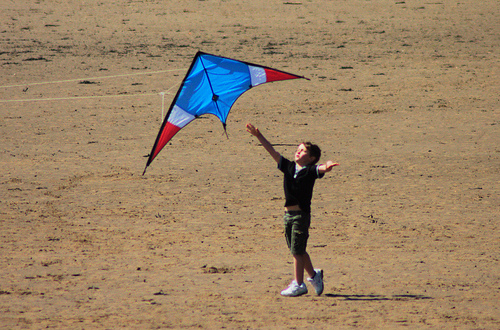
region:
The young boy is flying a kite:
[148, 42, 373, 313]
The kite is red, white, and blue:
[141, 43, 316, 153]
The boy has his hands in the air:
[235, 111, 347, 187]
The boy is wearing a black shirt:
[260, 157, 326, 207]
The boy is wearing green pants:
[266, 210, 312, 255]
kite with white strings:
[0, 51, 308, 177]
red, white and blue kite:
[144, 49, 309, 176]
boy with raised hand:
[246, 124, 337, 296]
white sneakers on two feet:
[282, 269, 324, 298]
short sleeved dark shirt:
[278, 159, 322, 209]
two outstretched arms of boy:
[244, 122, 338, 178]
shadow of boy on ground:
[325, 292, 430, 302]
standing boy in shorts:
[246, 125, 340, 297]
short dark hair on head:
[294, 141, 320, 165]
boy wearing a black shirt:
[263, 157, 322, 212]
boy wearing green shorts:
[272, 208, 318, 261]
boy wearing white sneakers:
[274, 267, 330, 295]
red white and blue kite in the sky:
[129, 34, 313, 168]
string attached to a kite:
[11, 51, 190, 116]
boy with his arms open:
[239, 113, 344, 188]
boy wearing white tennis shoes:
[277, 260, 327, 297]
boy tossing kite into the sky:
[242, 119, 337, 300]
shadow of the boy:
[320, 289, 426, 311]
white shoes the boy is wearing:
[280, 262, 330, 297]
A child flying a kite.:
[148, 45, 354, 305]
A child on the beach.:
[247, 118, 350, 303]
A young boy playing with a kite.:
[130, 48, 339, 297]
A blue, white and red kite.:
[140, 40, 314, 172]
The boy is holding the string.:
[242, 119, 346, 300]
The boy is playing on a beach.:
[88, 19, 430, 320]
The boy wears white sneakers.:
[247, 120, 339, 300]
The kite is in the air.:
[141, 41, 300, 175]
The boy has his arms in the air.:
[235, 114, 368, 304]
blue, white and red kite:
[132, 45, 314, 181]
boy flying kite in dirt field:
[135, 40, 344, 307]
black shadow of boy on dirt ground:
[321, 280, 435, 308]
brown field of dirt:
[2, 1, 499, 328]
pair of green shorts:
[280, 205, 315, 260]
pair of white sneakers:
[276, 265, 329, 300]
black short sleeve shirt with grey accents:
[274, 150, 327, 215]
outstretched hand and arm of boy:
[241, 119, 291, 179]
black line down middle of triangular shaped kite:
[196, 48, 233, 140]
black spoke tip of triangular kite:
[136, 164, 150, 179]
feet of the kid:
[259, 257, 341, 316]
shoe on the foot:
[271, 270, 315, 305]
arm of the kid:
[313, 140, 354, 192]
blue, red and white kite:
[118, 90, 235, 180]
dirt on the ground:
[115, 225, 237, 299]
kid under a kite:
[198, 101, 377, 291]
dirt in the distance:
[325, 3, 440, 78]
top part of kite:
[176, 33, 223, 78]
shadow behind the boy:
[332, 288, 441, 309]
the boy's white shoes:
[287, 271, 331, 297]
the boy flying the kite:
[243, 117, 343, 298]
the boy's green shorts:
[278, 212, 320, 256]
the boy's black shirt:
[280, 165, 308, 200]